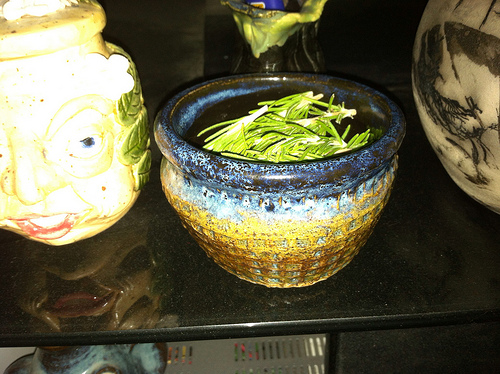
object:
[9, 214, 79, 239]
lips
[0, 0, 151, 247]
vase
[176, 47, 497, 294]
owl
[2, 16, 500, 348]
black table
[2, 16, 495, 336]
table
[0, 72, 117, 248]
face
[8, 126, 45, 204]
nose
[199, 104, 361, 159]
pine needles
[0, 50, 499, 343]
shelf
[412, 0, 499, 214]
ceramic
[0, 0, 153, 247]
ceramic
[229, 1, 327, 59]
leaf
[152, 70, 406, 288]
vase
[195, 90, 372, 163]
grass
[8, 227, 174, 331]
reflection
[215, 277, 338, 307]
reflection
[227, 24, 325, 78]
reflection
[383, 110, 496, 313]
reflection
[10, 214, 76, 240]
mouth